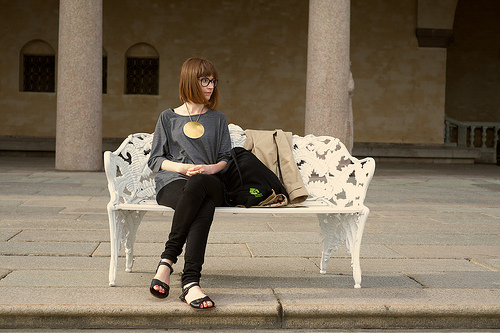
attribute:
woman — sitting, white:
[147, 54, 244, 314]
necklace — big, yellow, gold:
[178, 99, 210, 140]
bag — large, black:
[220, 144, 290, 206]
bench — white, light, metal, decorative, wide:
[100, 127, 381, 291]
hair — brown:
[177, 56, 219, 109]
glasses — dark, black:
[196, 76, 217, 88]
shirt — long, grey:
[147, 102, 234, 193]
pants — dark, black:
[154, 171, 237, 285]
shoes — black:
[147, 257, 216, 310]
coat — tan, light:
[241, 124, 309, 208]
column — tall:
[53, 1, 109, 174]